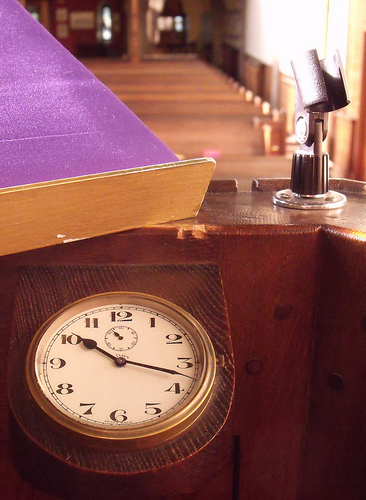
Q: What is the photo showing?
A: It is showing a church.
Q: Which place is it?
A: It is a church.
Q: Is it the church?
A: Yes, it is the church.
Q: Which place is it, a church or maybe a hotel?
A: It is a church.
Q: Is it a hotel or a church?
A: It is a church.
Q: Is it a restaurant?
A: No, it is a church.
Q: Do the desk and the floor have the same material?
A: Yes, both the desk and the floor are made of wood.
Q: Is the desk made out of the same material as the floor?
A: Yes, both the desk and the floor are made of wood.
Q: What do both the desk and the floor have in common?
A: The material, both the desk and the floor are wooden.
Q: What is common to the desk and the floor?
A: The material, both the desk and the floor are wooden.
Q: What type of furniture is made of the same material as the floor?
A: The desk is made of the same material as the floor.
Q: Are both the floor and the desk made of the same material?
A: Yes, both the floor and the desk are made of wood.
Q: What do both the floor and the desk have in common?
A: The material, both the floor and the desk are wooden.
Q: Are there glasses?
A: No, there are no glasses.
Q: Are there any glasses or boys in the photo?
A: No, there are no glasses or boys.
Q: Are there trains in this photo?
A: No, there are no trains.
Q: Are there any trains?
A: No, there are no trains.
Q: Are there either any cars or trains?
A: No, there are no trains or cars.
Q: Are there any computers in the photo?
A: No, there are no computers.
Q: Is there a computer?
A: No, there are no computers.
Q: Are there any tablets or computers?
A: No, there are no computers or tablets.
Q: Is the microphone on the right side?
A: Yes, the microphone is on the right of the image.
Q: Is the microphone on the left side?
A: No, the microphone is on the right of the image.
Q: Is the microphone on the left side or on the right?
A: The microphone is on the right of the image.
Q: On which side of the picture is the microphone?
A: The microphone is on the right of the image.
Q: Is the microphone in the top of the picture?
A: Yes, the microphone is in the top of the image.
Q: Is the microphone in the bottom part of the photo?
A: No, the microphone is in the top of the image.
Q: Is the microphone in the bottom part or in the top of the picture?
A: The microphone is in the top of the image.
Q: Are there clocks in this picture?
A: Yes, there is a clock.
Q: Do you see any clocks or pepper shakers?
A: Yes, there is a clock.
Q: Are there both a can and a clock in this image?
A: No, there is a clock but no cans.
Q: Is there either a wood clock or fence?
A: Yes, there is a wood clock.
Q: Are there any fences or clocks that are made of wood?
A: Yes, the clock is made of wood.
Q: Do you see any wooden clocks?
A: Yes, there is a wood clock.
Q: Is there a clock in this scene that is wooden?
A: Yes, there is a clock that is wooden.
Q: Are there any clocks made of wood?
A: Yes, there is a clock that is made of wood.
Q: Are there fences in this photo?
A: No, there are no fences.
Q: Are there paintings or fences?
A: No, there are no fences or paintings.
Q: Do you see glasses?
A: No, there are no glasses.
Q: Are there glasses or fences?
A: No, there are no glasses or fences.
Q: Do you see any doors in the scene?
A: Yes, there is a door.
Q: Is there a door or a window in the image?
A: Yes, there is a door.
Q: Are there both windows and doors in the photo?
A: Yes, there are both a door and windows.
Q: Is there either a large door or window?
A: Yes, there is a large door.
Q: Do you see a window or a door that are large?
A: Yes, the door is large.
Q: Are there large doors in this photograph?
A: Yes, there is a large door.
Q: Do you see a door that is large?
A: Yes, there is a door that is large.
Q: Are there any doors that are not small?
A: Yes, there is a large door.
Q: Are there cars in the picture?
A: No, there are no cars.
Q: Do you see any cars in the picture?
A: No, there are no cars.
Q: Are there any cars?
A: No, there are no cars.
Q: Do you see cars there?
A: No, there are no cars.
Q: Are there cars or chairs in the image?
A: No, there are no cars or chairs.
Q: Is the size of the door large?
A: Yes, the door is large.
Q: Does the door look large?
A: Yes, the door is large.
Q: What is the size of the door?
A: The door is large.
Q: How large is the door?
A: The door is large.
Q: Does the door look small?
A: No, the door is large.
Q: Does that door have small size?
A: No, the door is large.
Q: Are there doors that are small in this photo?
A: No, there is a door but it is large.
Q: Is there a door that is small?
A: No, there is a door but it is large.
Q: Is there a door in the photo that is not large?
A: No, there is a door but it is large.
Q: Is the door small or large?
A: The door is large.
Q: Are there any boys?
A: No, there are no boys.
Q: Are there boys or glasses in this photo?
A: No, there are no boys or glasses.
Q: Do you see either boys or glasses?
A: No, there are no boys or glasses.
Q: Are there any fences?
A: No, there are no fences.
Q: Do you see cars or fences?
A: No, there are no fences or cars.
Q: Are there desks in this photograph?
A: Yes, there is a desk.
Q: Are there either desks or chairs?
A: Yes, there is a desk.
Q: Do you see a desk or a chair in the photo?
A: Yes, there is a desk.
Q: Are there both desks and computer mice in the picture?
A: No, there is a desk but no computer mice.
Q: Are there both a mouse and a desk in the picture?
A: No, there is a desk but no computer mice.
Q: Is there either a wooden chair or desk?
A: Yes, there is a wood desk.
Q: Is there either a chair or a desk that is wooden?
A: Yes, the desk is wooden.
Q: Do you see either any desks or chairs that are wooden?
A: Yes, the desk is wooden.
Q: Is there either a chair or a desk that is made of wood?
A: Yes, the desk is made of wood.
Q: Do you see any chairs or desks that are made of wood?
A: Yes, the desk is made of wood.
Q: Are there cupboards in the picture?
A: No, there are no cupboards.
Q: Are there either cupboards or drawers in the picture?
A: No, there are no cupboards or drawers.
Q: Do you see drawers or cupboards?
A: No, there are no cupboards or drawers.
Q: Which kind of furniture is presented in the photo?
A: The furniture is a desk.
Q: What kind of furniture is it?
A: The piece of furniture is a desk.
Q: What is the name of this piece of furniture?
A: That is a desk.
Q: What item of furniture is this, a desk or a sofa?
A: That is a desk.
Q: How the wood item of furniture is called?
A: The piece of furniture is a desk.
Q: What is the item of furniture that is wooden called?
A: The piece of furniture is a desk.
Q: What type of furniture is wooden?
A: The furniture is a desk.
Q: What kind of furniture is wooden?
A: The furniture is a desk.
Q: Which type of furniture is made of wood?
A: The furniture is a desk.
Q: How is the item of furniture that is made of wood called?
A: The piece of furniture is a desk.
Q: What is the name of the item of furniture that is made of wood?
A: The piece of furniture is a desk.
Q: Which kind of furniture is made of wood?
A: The furniture is a desk.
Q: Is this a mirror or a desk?
A: This is a desk.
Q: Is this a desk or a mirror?
A: This is a desk.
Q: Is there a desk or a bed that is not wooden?
A: No, there is a desk but it is wooden.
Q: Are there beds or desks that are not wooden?
A: No, there is a desk but it is wooden.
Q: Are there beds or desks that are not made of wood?
A: No, there is a desk but it is made of wood.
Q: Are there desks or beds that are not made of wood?
A: No, there is a desk but it is made of wood.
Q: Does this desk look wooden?
A: Yes, the desk is wooden.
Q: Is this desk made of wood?
A: Yes, the desk is made of wood.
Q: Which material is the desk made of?
A: The desk is made of wood.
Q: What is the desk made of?
A: The desk is made of wood.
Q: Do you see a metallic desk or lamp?
A: No, there is a desk but it is wooden.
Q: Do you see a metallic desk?
A: No, there is a desk but it is wooden.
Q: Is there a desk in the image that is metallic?
A: No, there is a desk but it is wooden.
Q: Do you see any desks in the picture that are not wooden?
A: No, there is a desk but it is wooden.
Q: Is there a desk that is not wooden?
A: No, there is a desk but it is wooden.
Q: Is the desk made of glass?
A: No, the desk is made of wood.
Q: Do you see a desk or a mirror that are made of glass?
A: No, there is a desk but it is made of wood.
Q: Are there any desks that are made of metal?
A: No, there is a desk but it is made of wood.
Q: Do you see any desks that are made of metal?
A: No, there is a desk but it is made of wood.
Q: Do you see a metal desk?
A: No, there is a desk but it is made of wood.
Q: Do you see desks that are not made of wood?
A: No, there is a desk but it is made of wood.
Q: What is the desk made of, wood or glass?
A: The desk is made of wood.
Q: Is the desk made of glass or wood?
A: The desk is made of wood.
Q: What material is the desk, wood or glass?
A: The desk is made of wood.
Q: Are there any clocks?
A: Yes, there is a clock.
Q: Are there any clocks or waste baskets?
A: Yes, there is a clock.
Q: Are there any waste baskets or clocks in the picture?
A: Yes, there is a clock.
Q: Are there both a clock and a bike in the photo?
A: No, there is a clock but no bikes.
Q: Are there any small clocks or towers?
A: Yes, there is a small clock.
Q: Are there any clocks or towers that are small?
A: Yes, the clock is small.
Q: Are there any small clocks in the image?
A: Yes, there is a small clock.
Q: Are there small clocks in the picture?
A: Yes, there is a small clock.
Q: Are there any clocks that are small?
A: Yes, there is a clock that is small.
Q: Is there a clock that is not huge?
A: Yes, there is a small clock.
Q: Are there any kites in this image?
A: No, there are no kites.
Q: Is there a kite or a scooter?
A: No, there are no kites or scooters.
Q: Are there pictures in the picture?
A: No, there are no pictures.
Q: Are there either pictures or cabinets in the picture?
A: No, there are no pictures or cabinets.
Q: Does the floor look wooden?
A: Yes, the floor is wooden.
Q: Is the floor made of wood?
A: Yes, the floor is made of wood.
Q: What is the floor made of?
A: The floor is made of wood.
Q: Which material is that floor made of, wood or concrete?
A: The floor is made of wood.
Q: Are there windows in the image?
A: Yes, there is a window.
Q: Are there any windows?
A: Yes, there is a window.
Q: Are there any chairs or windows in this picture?
A: Yes, there is a window.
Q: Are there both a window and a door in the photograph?
A: Yes, there are both a window and a door.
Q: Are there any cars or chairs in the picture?
A: No, there are no cars or chairs.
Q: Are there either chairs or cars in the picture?
A: No, there are no cars or chairs.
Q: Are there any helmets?
A: No, there are no helmets.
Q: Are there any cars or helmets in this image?
A: No, there are no helmets or cars.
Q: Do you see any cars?
A: No, there are no cars.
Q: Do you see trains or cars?
A: No, there are no cars or trains.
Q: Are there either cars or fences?
A: No, there are no fences or cars.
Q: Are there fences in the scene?
A: No, there are no fences.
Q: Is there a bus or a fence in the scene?
A: No, there are no fences or buses.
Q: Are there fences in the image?
A: No, there are no fences.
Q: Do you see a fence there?
A: No, there are no fences.